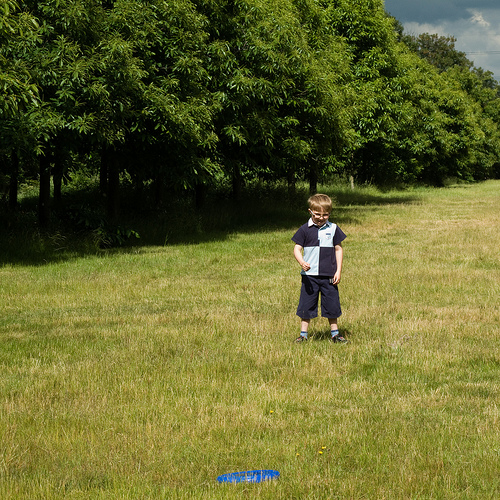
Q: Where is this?
A: This is at the field.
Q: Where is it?
A: This is at the field.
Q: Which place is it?
A: It is a field.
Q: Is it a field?
A: Yes, it is a field.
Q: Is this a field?
A: Yes, it is a field.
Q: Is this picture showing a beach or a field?
A: It is showing a field.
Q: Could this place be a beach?
A: No, it is a field.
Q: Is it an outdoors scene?
A: Yes, it is outdoors.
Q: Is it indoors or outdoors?
A: It is outdoors.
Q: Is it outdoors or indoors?
A: It is outdoors.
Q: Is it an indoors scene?
A: No, it is outdoors.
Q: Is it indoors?
A: No, it is outdoors.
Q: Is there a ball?
A: No, there are no balls.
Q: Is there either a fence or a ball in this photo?
A: No, there are no balls or fences.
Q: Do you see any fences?
A: No, there are no fences.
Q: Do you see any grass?
A: Yes, there is grass.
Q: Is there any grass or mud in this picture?
A: Yes, there is grass.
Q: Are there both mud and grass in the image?
A: No, there is grass but no mud.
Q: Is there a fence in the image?
A: No, there are no fences.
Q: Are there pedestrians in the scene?
A: No, there are no pedestrians.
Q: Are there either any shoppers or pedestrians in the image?
A: No, there are no pedestrians or shoppers.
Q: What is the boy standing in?
A: The boy is standing in the grass.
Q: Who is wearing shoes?
A: The boy is wearing shoes.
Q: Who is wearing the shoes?
A: The boy is wearing shoes.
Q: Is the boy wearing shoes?
A: Yes, the boy is wearing shoes.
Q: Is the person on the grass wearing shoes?
A: Yes, the boy is wearing shoes.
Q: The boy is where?
A: The boy is on the grass.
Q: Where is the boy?
A: The boy is on the grass.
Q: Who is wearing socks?
A: The boy is wearing socks.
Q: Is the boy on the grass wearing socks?
A: Yes, the boy is wearing socks.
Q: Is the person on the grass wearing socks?
A: Yes, the boy is wearing socks.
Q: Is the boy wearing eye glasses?
A: No, the boy is wearing socks.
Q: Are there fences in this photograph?
A: No, there are no fences.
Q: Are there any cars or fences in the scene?
A: No, there are no fences or cars.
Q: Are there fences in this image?
A: No, there are no fences.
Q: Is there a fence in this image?
A: No, there are no fences.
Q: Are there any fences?
A: No, there are no fences.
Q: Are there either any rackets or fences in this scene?
A: No, there are no fences or rackets.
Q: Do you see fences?
A: No, there are no fences.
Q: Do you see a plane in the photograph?
A: No, there are no airplanes.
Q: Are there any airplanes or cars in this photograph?
A: No, there are no airplanes or cars.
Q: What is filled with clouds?
A: The sky is filled with clouds.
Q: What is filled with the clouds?
A: The sky is filled with clouds.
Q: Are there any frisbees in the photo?
A: Yes, there is a frisbee.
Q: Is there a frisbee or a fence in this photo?
A: Yes, there is a frisbee.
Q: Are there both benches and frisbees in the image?
A: No, there is a frisbee but no benches.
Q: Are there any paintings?
A: No, there are no paintings.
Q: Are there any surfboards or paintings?
A: No, there are no paintings or surfboards.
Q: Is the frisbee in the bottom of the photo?
A: Yes, the frisbee is in the bottom of the image.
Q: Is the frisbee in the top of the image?
A: No, the frisbee is in the bottom of the image.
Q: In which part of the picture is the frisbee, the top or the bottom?
A: The frisbee is in the bottom of the image.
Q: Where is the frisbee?
A: The frisbee is in the grass.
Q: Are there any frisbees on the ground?
A: Yes, there is a frisbee on the ground.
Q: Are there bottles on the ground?
A: No, there is a frisbee on the ground.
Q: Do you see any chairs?
A: No, there are no chairs.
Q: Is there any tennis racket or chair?
A: No, there are no chairs or rackets.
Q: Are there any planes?
A: No, there are no planes.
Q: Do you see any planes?
A: No, there are no planes.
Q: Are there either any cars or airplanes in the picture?
A: No, there are no airplanes or cars.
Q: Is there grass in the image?
A: Yes, there is grass.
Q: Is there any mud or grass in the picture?
A: Yes, there is grass.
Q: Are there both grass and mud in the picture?
A: No, there is grass but no mud.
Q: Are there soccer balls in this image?
A: No, there are no soccer balls.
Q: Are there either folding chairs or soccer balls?
A: No, there are no soccer balls or folding chairs.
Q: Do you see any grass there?
A: Yes, there is grass.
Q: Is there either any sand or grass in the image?
A: Yes, there is grass.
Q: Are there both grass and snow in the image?
A: No, there is grass but no snow.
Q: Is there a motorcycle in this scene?
A: No, there are no motorcycles.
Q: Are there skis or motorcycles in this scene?
A: No, there are no motorcycles or skis.